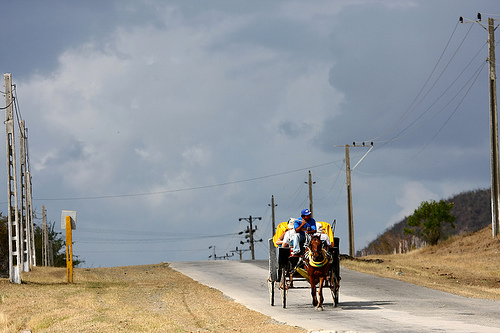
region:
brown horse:
[311, 226, 337, 298]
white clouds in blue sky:
[49, 32, 101, 103]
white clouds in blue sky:
[100, 122, 159, 185]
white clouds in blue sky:
[107, 194, 149, 233]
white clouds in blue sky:
[118, 42, 164, 79]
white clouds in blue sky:
[40, 76, 115, 133]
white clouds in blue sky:
[192, 18, 233, 54]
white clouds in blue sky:
[232, 1, 301, 81]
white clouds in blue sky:
[363, 17, 428, 70]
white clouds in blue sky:
[131, 18, 187, 68]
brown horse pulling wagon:
[266, 217, 351, 313]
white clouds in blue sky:
[28, 21, 62, 62]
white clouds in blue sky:
[315, 48, 346, 94]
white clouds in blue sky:
[172, 63, 208, 108]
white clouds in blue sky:
[192, 194, 236, 239]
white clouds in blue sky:
[114, 123, 134, 151]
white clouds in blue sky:
[119, 138, 176, 185]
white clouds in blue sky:
[414, 53, 464, 105]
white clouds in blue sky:
[125, 59, 183, 103]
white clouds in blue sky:
[65, 147, 129, 197]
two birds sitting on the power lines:
[457, 13, 482, 22]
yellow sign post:
[65, 216, 72, 281]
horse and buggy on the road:
[267, 235, 340, 307]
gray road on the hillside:
[170, 260, 497, 332]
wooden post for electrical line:
[343, 144, 354, 252]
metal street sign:
[60, 210, 77, 229]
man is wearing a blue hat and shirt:
[292, 210, 315, 253]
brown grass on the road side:
[4, 262, 292, 331]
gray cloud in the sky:
[317, 8, 494, 154]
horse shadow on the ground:
[331, 298, 386, 313]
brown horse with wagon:
[272, 216, 336, 295]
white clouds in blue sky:
[78, 108, 117, 166]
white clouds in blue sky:
[80, 186, 135, 227]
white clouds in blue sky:
[115, 68, 175, 125]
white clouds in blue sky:
[112, 160, 160, 203]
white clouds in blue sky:
[184, 49, 231, 109]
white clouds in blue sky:
[278, 81, 348, 147]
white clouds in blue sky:
[377, 54, 413, 86]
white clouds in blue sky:
[377, 118, 422, 174]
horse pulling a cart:
[257, 203, 346, 310]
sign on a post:
[54, 205, 79, 288]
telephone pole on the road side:
[339, 137, 379, 261]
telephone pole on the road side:
[301, 165, 321, 212]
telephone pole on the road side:
[265, 189, 279, 236]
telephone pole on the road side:
[236, 212, 263, 261]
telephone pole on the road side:
[458, 10, 498, 245]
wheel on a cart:
[277, 265, 291, 309]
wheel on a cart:
[265, 263, 274, 305]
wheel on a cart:
[327, 271, 345, 305]